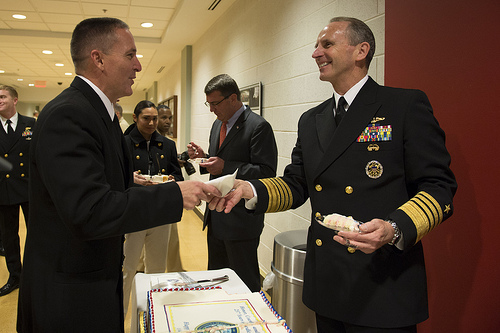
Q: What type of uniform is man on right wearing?
A: A military uniform.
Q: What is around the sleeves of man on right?
A: Gold stripe braiding.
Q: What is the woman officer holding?
A: A plate of food.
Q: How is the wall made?
A: Made of concrete blocks.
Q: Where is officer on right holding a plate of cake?
A: In his left hand.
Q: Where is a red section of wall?
A: In foreground on right.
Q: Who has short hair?
A: The men.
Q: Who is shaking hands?
A: Two men.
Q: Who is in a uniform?
A: A man.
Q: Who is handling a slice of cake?
A: A man.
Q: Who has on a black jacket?
A: A woman.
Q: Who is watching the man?
A: A woman.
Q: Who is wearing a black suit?
A: A man.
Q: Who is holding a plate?
A: A man.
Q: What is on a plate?
A: Food.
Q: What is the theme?
A: Military.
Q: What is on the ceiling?
A: Lights.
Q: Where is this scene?
A: Inside building.